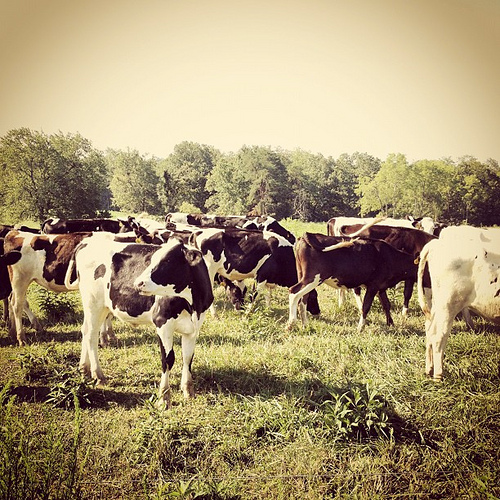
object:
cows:
[289, 224, 422, 326]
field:
[2, 167, 105, 436]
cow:
[65, 228, 216, 409]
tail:
[62, 237, 83, 292]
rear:
[70, 235, 106, 282]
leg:
[152, 326, 178, 402]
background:
[6, 6, 491, 210]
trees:
[10, 126, 58, 225]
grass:
[222, 376, 491, 498]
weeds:
[331, 384, 392, 441]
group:
[320, 202, 498, 359]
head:
[132, 242, 197, 299]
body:
[68, 237, 207, 329]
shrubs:
[456, 166, 484, 220]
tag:
[179, 249, 197, 260]